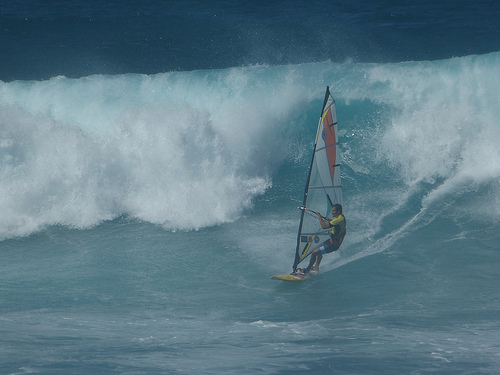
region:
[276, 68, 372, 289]
a person sailing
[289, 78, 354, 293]
a sail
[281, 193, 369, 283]
a person holding onto a sail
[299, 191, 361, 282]
a man riding on the water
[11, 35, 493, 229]
a huge wave in the ocean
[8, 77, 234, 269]
froth in the water from the ocean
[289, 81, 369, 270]
a white and red sail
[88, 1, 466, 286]
a person riding down a wave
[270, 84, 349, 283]
The man is parasailing.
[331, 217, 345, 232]
The shirt is yellow.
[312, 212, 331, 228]
The man grips the parasail.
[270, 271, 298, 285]
The surfboard is yellow.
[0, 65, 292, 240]
A wave is behind the man.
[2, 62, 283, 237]
The wave is large.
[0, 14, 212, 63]
The water is blue.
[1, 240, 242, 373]
calm ocean water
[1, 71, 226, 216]
large ocean wave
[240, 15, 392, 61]
mist from water wave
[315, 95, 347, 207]
sail used for sailing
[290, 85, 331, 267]
pole used for holding sail upright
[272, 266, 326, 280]
board for sailor to stand on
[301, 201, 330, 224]
handle for sailor to hold onto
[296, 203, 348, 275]
man pulling back on sail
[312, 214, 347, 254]
wet suit to cover sailor's bod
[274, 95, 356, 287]
the surfboard has a sail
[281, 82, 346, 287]
the surfboard has a mast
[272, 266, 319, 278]
the surfboard is made of wood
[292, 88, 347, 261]
a sail is attached to the mast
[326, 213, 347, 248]
the man is wearing a short sleeve shirt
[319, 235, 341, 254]
the man is wearing shorts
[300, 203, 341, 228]
the man is holding on to the sail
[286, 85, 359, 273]
the mast is at an angle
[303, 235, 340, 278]
the man has his knees bent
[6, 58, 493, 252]
a large wave is behing the surfer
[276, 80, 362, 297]
man windsurfing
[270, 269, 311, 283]
board sticking out of the water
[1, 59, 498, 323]
large wave in the water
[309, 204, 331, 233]
hands on the pole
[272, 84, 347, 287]
sail sticking out of the board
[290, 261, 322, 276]
feet planted on the board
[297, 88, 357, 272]
red and white sail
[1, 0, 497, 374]
a body of water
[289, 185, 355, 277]
man is leaning back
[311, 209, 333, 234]
arm bent at the elbow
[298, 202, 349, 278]
a person is standing up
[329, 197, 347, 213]
man has wet hair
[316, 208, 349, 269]
man is wearing a wetsuit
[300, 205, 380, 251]
wetsuit is yellow and blue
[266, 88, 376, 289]
boat has a man on it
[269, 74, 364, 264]
boat has a big sail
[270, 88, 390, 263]
sail is white in color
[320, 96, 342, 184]
orange swoosh on sail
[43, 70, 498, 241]
water is making a wave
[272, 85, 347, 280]
the man holding onto the sail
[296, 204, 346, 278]
the man wearing a wet suit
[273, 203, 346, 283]
the man standing on the board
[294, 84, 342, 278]
the sail is colorful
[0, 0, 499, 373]
the man is on the water